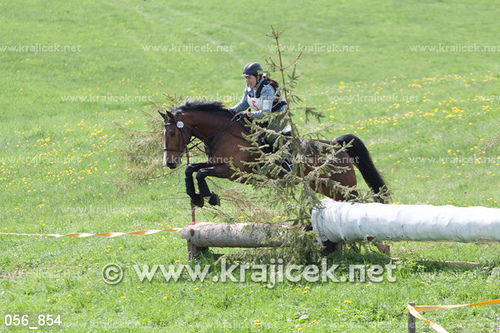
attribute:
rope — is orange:
[43, 221, 180, 248]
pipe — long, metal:
[281, 199, 496, 260]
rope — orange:
[75, 216, 192, 254]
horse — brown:
[159, 94, 397, 232]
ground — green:
[438, 150, 453, 177]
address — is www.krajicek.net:
[131, 255, 399, 290]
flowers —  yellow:
[5, 58, 173, 209]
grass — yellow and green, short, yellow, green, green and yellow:
[3, 4, 492, 331]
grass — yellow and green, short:
[2, 1, 498, 154]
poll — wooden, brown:
[178, 208, 318, 258]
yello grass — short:
[354, 75, 416, 134]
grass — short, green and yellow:
[342, 53, 489, 172]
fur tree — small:
[223, 25, 392, 268]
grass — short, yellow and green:
[121, 41, 180, 66]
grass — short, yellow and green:
[152, 293, 316, 328]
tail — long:
[337, 128, 399, 203]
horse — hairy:
[159, 91, 383, 251]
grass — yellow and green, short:
[44, 37, 106, 109]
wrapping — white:
[308, 195, 498, 250]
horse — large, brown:
[135, 82, 447, 282]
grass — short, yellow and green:
[398, 62, 458, 117]